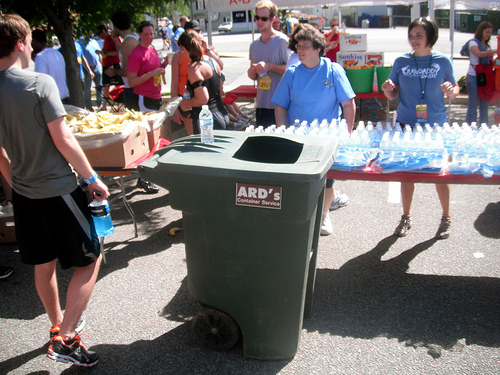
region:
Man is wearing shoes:
[42, 310, 104, 370]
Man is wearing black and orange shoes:
[45, 310, 102, 370]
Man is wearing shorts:
[10, 179, 109, 266]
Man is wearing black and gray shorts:
[8, 182, 105, 269]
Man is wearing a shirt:
[0, 65, 85, 200]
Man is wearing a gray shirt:
[0, 62, 80, 201]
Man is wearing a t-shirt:
[0, 60, 84, 200]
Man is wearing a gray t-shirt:
[0, 59, 85, 201]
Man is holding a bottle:
[86, 190, 117, 242]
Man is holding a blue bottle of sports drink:
[82, 185, 122, 246]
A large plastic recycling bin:
[137, 125, 342, 362]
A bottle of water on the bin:
[196, 103, 216, 145]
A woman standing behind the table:
[380, 15, 460, 240]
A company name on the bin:
[232, 181, 285, 211]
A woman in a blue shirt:
[271, 28, 361, 137]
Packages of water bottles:
[247, 115, 497, 176]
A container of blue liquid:
[86, 188, 116, 238]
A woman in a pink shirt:
[124, 18, 169, 113]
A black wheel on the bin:
[188, 306, 242, 353]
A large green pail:
[342, 65, 374, 92]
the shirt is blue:
[264, 60, 362, 134]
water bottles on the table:
[242, 105, 490, 202]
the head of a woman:
[283, 26, 336, 68]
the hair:
[276, 8, 358, 84]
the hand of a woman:
[377, 73, 402, 99]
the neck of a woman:
[399, 28, 449, 63]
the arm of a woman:
[263, 60, 310, 127]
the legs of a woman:
[383, 165, 450, 270]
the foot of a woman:
[373, 196, 422, 257]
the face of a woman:
[380, 0, 472, 75]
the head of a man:
[3, 10, 70, 79]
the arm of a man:
[43, 97, 128, 205]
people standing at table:
[170, 0, 483, 265]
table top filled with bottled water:
[187, 75, 497, 200]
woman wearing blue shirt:
[268, 58, 373, 124]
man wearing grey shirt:
[1, 70, 106, 211]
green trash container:
[126, 69, 354, 367]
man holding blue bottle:
[1, 2, 146, 276]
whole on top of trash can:
[104, 96, 404, 372]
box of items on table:
[6, 49, 165, 188]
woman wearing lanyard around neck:
[393, 43, 445, 128]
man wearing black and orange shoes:
[22, 313, 101, 373]